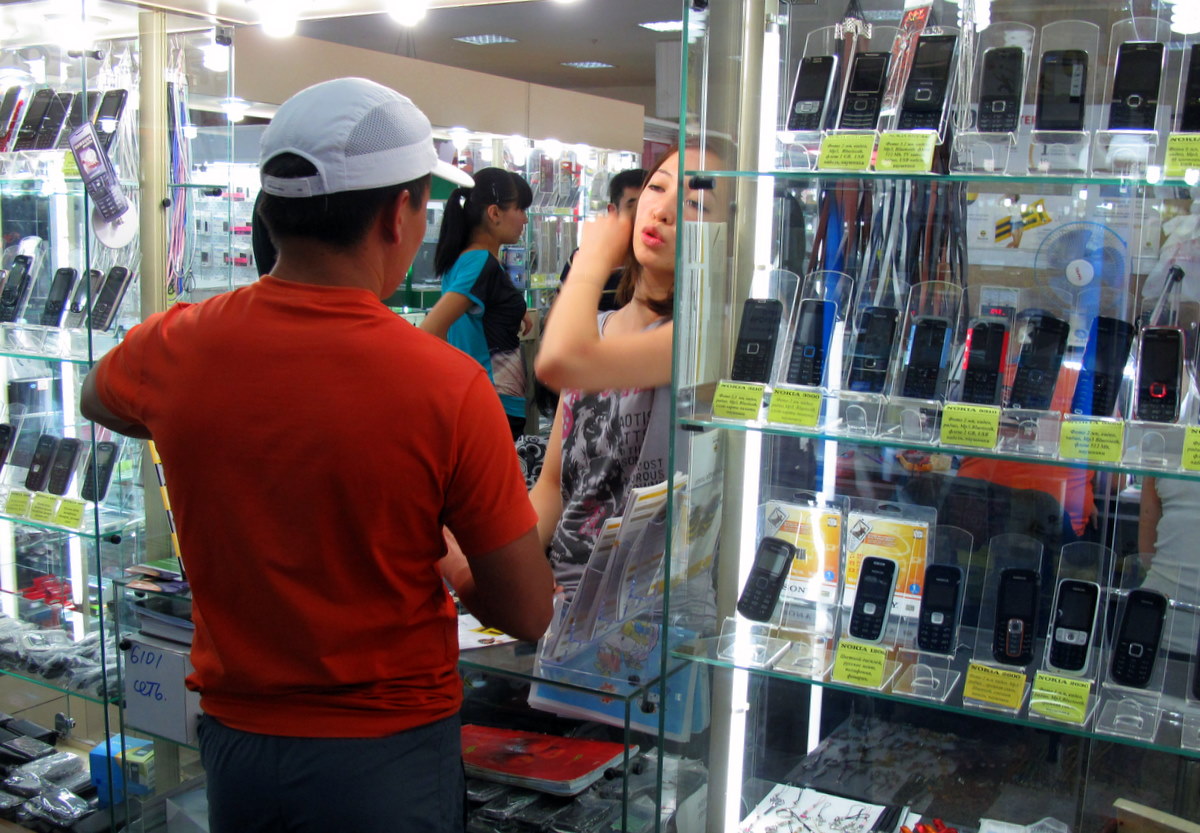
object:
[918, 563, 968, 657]
phones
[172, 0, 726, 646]
window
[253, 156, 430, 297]
head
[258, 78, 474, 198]
cap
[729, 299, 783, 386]
phone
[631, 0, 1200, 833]
case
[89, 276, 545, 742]
shirt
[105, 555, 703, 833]
counter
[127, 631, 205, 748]
box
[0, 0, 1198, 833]
store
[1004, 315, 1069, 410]
phones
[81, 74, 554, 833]
man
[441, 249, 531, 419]
shirt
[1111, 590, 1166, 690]
phones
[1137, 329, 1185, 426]
phones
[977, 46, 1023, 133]
phones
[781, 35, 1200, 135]
row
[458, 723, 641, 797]
book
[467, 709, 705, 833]
shelf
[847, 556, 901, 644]
phones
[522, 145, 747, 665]
woman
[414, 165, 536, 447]
woman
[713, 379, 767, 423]
paper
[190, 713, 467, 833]
pants